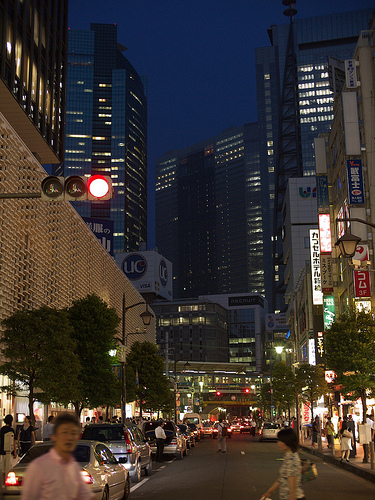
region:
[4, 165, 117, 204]
a horizontal traffic light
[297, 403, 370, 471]
people walking on sidewalk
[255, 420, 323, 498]
woman with black hair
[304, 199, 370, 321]
advertisements on the buildings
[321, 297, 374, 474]
a green tree in front a building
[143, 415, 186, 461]
people behind a car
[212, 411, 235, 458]
man carrying a backpack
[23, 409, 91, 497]
a man in a white button down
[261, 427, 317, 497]
an asian woman walking across a street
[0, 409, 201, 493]
a row of cars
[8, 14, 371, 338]
a bright city skyline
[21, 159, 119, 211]
a streetlight with a red light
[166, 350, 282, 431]
a short white stone building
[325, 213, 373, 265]
a lantern hanging over a street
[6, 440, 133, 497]
a car pulls into a parking space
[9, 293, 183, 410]
trees in the middle of a city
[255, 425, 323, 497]
Lady walking across the streetq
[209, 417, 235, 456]
Man with backpack crossing street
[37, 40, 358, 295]
skyscrapers overlooking city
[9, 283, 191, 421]
Trees sitting in front of building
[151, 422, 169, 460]
Man in white shirt opening trunk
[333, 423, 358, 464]
Lady at the side looking right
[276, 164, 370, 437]
street signs cover the buildings.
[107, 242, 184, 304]
Billboard shown above the street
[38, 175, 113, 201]
red traffic light is lit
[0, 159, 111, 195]
traffic light anchored to metal pole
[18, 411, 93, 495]
man wearing pink shirt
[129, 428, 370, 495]
white painted line on black street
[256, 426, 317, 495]
woman carry green shoulder bag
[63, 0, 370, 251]
dark blue night sky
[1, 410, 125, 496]
small silver car parked behind man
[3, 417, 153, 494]
gray suv parked in front of small car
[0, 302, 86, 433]
green tree next to suv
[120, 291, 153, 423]
lamp hanging from black metal pole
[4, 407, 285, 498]
Cars on a city street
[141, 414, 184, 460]
Man standing by open trunk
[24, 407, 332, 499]
People are walking in the road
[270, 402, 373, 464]
The sidewalks are crowded with people.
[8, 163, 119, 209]
The traffic signal is red.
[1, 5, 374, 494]
A city scene.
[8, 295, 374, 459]
Trees on the sidewalks.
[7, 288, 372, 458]
Small trees with green leaves.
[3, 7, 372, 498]
A nighttime city scene.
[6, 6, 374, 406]
Lights are on in the buildings.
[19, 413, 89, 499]
A man with a pink shirt.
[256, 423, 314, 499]
A woman in a dress shirt.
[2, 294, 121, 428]
A tree with lots of green leaves.